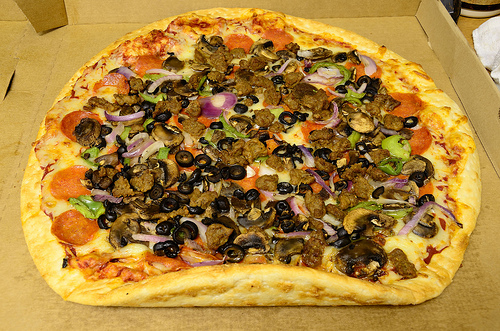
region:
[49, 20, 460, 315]
a beautiful delicious food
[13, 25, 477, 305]
a hot looking food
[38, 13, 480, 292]
the tasty looking pizza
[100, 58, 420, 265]
a hot beautiful design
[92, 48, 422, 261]
cute designs on pizza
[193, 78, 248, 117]
a piece of onion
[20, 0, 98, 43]
a small part of box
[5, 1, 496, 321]
a box containing pizza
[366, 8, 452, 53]
the empty space of the box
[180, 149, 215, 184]
a small pieces of decorative items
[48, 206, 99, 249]
pepperoni is curling on edge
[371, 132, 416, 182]
green peppers, light+dark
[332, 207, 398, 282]
mushroom slices, various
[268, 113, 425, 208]
olive slice chunks, black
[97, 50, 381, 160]
onion of red[dish purple] in thin slice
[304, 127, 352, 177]
is it a steakball this way comes?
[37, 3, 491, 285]
a spritz or two of pizza sauce below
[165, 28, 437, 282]
melted mozzarella, if you look hard enough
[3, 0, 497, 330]
a cardboard box with warm oil embedded from nether side of crust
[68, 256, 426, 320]
nether side of crust folded over, demonstrating no burn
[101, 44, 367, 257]
this is a pizza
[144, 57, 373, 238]
the pizza is spicy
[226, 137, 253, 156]
the spices are brown in color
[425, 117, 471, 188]
the pizza is big in size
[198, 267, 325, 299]
the pizza is folded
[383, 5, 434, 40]
this is a box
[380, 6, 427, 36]
the box is open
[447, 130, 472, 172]
the pizza is yellow in color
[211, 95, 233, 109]
this is the onion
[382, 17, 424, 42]
the box is brown in color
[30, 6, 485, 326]
A pizza.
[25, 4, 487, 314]
The pizza has a lot of toppings.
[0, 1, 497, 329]
The pizza is on a box.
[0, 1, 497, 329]
The box is made of cardboard.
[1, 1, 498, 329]
The cardboard is brown.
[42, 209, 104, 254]
A piece of pepperoni/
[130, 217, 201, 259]
A lot of olives are on the pizza.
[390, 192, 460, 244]
The purple pieces are onions.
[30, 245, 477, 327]
The pizza is folded at the bottom.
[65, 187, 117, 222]
A basil leaf.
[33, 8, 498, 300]
Large round pizza in a box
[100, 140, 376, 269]
Lots of black olives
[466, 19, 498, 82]
White towel next to box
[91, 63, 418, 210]
Slices of red onion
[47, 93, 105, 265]
Pepperoni by the edge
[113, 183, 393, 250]
Mushrooms on the pizza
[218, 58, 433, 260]
Green bell pepper on pizza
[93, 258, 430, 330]
One edge of pizz is turned up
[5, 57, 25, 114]
A slit in the cardboard box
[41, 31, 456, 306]
A pizza with lots of toppings